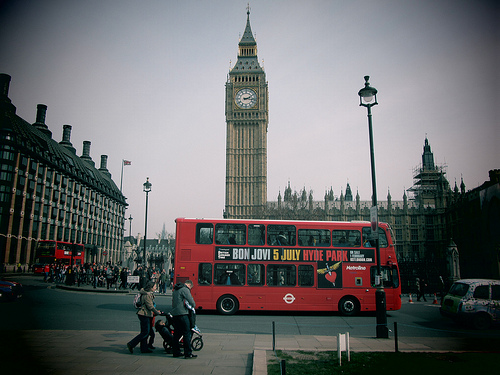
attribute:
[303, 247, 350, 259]
lettering — red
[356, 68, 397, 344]
street light — not lit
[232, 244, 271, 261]
bon jovi — white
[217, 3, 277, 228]
big ben — tall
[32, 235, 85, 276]
bus — red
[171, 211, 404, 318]
bus — red, double decker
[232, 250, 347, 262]
text — many colors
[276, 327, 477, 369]
grass — wet, green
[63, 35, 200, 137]
sky — partly cloudy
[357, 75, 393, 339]
street lamp — tall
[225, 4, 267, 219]
tower — large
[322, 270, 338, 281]
heart — red